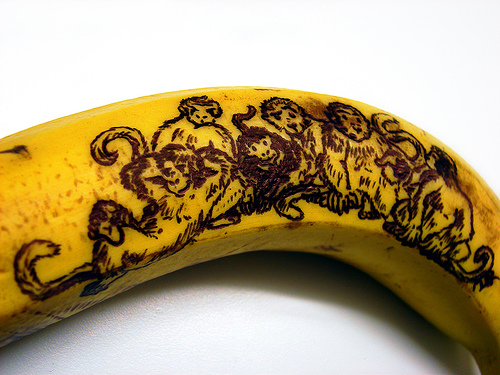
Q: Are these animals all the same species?
A: Yes, all the animals are monkeys.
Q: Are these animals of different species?
A: No, all the animals are monkeys.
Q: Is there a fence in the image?
A: No, there are no fences.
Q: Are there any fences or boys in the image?
A: No, there are no fences or boys.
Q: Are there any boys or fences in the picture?
A: No, there are no fences or boys.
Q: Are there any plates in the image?
A: Yes, there is a plate.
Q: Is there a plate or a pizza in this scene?
A: Yes, there is a plate.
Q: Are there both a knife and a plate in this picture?
A: No, there is a plate but no knives.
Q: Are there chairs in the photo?
A: No, there are no chairs.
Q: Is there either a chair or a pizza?
A: No, there are no chairs or pizzas.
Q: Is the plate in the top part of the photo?
A: No, the plate is in the bottom of the image.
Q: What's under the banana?
A: The plate is under the banana.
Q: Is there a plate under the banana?
A: Yes, there is a plate under the banana.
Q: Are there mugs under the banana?
A: No, there is a plate under the banana.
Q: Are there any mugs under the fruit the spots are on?
A: No, there is a plate under the banana.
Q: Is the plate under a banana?
A: Yes, the plate is under a banana.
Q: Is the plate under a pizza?
A: No, the plate is under a banana.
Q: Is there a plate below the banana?
A: Yes, there is a plate below the banana.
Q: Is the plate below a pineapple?
A: No, the plate is below the banana.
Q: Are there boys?
A: No, there are no boys.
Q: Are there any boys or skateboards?
A: No, there are no boys or skateboards.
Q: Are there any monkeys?
A: Yes, there is a monkey.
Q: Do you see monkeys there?
A: Yes, there is a monkey.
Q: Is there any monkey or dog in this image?
A: Yes, there is a monkey.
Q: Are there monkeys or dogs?
A: Yes, there is a monkey.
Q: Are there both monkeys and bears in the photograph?
A: No, there is a monkey but no bears.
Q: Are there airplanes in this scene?
A: No, there are no airplanes.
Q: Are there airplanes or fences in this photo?
A: No, there are no airplanes or fences.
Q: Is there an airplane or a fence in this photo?
A: No, there are no airplanes or fences.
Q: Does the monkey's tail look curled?
A: Yes, the tail is curled.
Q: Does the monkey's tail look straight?
A: No, the tail is curled.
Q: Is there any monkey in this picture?
A: Yes, there is a monkey.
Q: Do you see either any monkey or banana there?
A: Yes, there is a monkey.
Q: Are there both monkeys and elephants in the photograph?
A: No, there is a monkey but no elephants.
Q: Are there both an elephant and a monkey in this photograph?
A: No, there is a monkey but no elephants.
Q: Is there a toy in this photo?
A: No, there are no toys.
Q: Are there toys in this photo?
A: No, there are no toys.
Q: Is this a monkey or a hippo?
A: This is a monkey.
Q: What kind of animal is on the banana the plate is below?
A: The animal is a monkey.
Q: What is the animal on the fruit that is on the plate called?
A: The animal is a monkey.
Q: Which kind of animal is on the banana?
A: The animal is a monkey.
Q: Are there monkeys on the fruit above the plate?
A: Yes, there is a monkey on the banana.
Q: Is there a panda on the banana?
A: No, there is a monkey on the banana.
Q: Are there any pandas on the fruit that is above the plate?
A: No, there is a monkey on the banana.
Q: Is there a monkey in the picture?
A: Yes, there is a monkey.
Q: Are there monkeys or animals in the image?
A: Yes, there is a monkey.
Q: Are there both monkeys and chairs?
A: No, there is a monkey but no chairs.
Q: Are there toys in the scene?
A: No, there are no toys.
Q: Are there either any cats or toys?
A: No, there are no toys or cats.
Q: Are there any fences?
A: No, there are no fences.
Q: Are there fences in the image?
A: No, there are no fences.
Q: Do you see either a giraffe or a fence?
A: No, there are no fences or giraffes.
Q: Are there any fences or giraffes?
A: No, there are no fences or giraffes.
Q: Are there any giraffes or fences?
A: No, there are no fences or giraffes.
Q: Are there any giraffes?
A: No, there are no giraffes.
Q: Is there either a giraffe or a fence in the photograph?
A: No, there are no giraffes or fences.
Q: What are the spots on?
A: The spots are on the banana.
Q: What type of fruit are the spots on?
A: The spots are on the banana.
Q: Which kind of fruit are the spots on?
A: The spots are on the banana.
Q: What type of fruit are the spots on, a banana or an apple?
A: The spots are on a banana.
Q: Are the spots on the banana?
A: Yes, the spots are on the banana.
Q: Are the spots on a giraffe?
A: No, the spots are on the banana.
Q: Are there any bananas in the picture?
A: Yes, there is a banana.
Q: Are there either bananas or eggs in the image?
A: Yes, there is a banana.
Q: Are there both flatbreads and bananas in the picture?
A: No, there is a banana but no flatbreads.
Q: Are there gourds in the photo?
A: No, there are no gourds.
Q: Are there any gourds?
A: No, there are no gourds.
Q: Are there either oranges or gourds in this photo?
A: No, there are no gourds or oranges.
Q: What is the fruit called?
A: The fruit is a banana.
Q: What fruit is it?
A: The fruit is a banana.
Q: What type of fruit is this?
A: This is a banana.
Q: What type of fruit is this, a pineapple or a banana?
A: This is a banana.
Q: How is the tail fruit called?
A: The fruit is a banana.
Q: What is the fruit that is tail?
A: The fruit is a banana.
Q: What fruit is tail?
A: The fruit is a banana.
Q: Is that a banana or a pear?
A: That is a banana.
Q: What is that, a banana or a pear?
A: That is a banana.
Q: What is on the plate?
A: The banana is on the plate.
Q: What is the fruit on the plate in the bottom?
A: The fruit is a banana.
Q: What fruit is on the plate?
A: The fruit is a banana.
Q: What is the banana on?
A: The banana is on the plate.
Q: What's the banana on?
A: The banana is on the plate.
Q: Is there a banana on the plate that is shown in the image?
A: Yes, there is a banana on the plate.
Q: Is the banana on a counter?
A: No, the banana is on a plate.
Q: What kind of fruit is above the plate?
A: The fruit is a banana.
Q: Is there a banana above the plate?
A: Yes, there is a banana above the plate.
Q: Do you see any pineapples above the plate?
A: No, there is a banana above the plate.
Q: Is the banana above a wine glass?
A: No, the banana is above the plate.